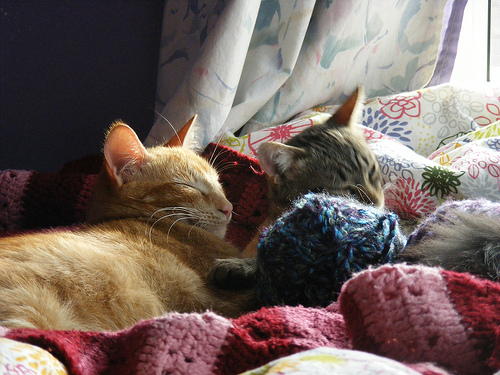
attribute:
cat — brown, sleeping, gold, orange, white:
[2, 112, 256, 374]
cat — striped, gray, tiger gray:
[212, 85, 499, 316]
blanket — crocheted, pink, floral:
[3, 265, 499, 374]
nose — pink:
[219, 200, 234, 218]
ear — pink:
[101, 118, 147, 185]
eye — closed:
[172, 178, 210, 199]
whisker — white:
[145, 202, 201, 224]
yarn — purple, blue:
[255, 190, 409, 308]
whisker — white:
[148, 210, 197, 244]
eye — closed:
[326, 184, 358, 195]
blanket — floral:
[216, 81, 499, 239]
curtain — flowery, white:
[141, 2, 468, 157]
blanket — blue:
[250, 187, 407, 318]